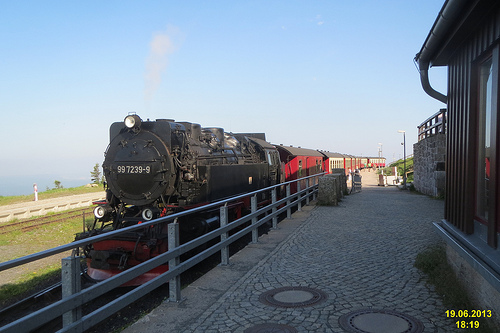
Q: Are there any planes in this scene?
A: No, there are no planes.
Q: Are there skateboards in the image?
A: No, there are no skateboards.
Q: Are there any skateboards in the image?
A: No, there are no skateboards.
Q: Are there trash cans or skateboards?
A: No, there are no skateboards or trash cans.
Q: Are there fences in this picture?
A: Yes, there is a fence.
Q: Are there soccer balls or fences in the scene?
A: Yes, there is a fence.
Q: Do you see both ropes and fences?
A: No, there is a fence but no ropes.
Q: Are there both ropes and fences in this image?
A: No, there is a fence but no ropes.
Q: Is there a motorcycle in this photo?
A: No, there are no motorcycles.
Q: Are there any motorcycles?
A: No, there are no motorcycles.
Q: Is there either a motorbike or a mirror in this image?
A: No, there are no motorcycles or mirrors.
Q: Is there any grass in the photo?
A: Yes, there is grass.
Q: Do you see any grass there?
A: Yes, there is grass.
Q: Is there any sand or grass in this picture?
A: Yes, there is grass.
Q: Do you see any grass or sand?
A: Yes, there is grass.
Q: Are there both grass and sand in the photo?
A: No, there is grass but no sand.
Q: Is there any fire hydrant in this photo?
A: No, there are no fire hydrants.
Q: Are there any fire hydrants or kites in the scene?
A: No, there are no fire hydrants or kites.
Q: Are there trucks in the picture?
A: No, there are no trucks.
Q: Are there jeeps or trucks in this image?
A: No, there are no trucks or jeeps.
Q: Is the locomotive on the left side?
A: Yes, the locomotive is on the left of the image.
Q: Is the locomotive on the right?
A: No, the locomotive is on the left of the image.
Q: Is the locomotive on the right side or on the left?
A: The locomotive is on the left of the image.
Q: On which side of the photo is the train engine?
A: The train engine is on the left of the image.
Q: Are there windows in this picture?
A: Yes, there is a window.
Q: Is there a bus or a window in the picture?
A: Yes, there is a window.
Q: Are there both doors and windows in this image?
A: No, there is a window but no doors.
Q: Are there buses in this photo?
A: No, there are no buses.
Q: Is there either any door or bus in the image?
A: No, there are no buses or doors.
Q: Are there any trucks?
A: No, there are no trucks.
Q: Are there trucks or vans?
A: No, there are no trucks or vans.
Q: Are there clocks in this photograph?
A: No, there are no clocks.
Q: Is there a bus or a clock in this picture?
A: No, there are no clocks or buses.